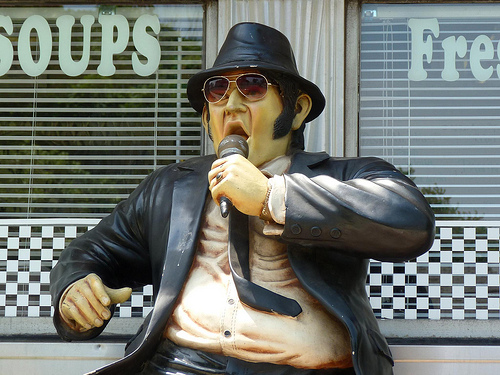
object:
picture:
[0, 0, 499, 375]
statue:
[48, 21, 439, 375]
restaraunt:
[1, 1, 498, 322]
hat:
[186, 21, 327, 124]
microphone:
[217, 134, 250, 219]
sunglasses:
[199, 72, 280, 104]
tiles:
[364, 225, 500, 320]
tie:
[226, 203, 306, 318]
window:
[0, 0, 210, 223]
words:
[0, 10, 166, 77]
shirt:
[159, 154, 356, 372]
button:
[223, 329, 233, 338]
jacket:
[44, 149, 437, 375]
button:
[290, 223, 303, 235]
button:
[310, 226, 323, 238]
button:
[329, 227, 342, 240]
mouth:
[221, 118, 252, 145]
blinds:
[0, 17, 207, 219]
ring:
[215, 172, 223, 184]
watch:
[261, 177, 275, 222]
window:
[355, 0, 498, 223]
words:
[403, 15, 498, 84]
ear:
[201, 102, 209, 134]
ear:
[289, 92, 313, 131]